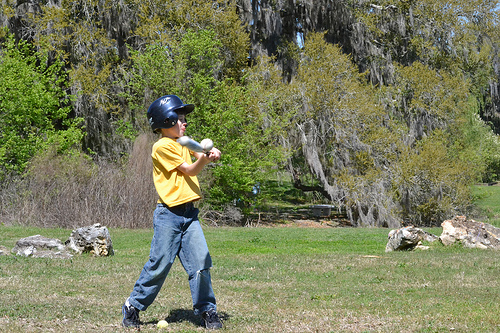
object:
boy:
[117, 94, 228, 333]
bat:
[176, 135, 218, 163]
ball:
[196, 137, 214, 153]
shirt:
[150, 137, 204, 208]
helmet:
[145, 94, 194, 134]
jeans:
[127, 203, 220, 316]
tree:
[69, 65, 114, 154]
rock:
[68, 223, 114, 255]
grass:
[0, 278, 121, 333]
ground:
[0, 173, 499, 333]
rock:
[9, 234, 76, 260]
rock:
[438, 215, 500, 249]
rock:
[382, 225, 439, 254]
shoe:
[119, 304, 144, 330]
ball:
[154, 319, 167, 329]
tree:
[103, 29, 305, 227]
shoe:
[197, 309, 225, 331]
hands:
[207, 147, 222, 160]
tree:
[0, 28, 95, 189]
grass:
[458, 181, 498, 227]